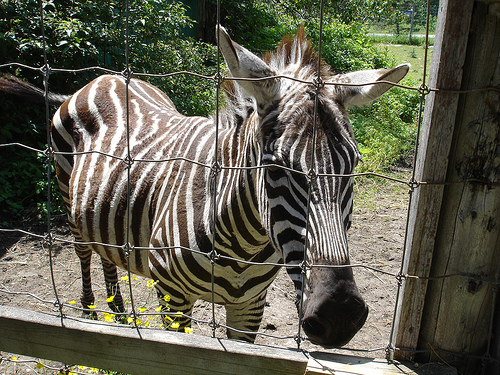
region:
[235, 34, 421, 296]
head of the zebra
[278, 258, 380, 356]
nose of the zebra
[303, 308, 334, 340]
nostril of the zebra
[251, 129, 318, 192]
eye of the animal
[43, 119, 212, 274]
black and white animal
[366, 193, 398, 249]
brown dirt under animal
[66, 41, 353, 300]
fence in front of animal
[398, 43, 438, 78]
green grass on the ground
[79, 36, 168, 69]
leaves on the tree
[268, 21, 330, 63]
hair on the zebra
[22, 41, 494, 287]
the zebra has stripes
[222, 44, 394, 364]
black and white zebra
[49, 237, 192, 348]
yellow flowers behind fence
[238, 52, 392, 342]
zebra looking at fence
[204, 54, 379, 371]
zebra in sunny scene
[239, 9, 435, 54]
green foliage behind fence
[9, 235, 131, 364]
sunlight on wooden post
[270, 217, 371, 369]
zebra's nose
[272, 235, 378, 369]
zebra's nose making shadow on wooden fence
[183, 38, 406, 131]
zebra's two ears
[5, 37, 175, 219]
zebra swishing tail in air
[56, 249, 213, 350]
small yellow flowers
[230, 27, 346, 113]
zebra has mohawk hair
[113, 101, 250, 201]
brown stripes not black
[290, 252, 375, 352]
zebras nose through the fence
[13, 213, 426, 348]
grass is dead near fence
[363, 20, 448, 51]
road or walk way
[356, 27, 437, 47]
over grown green grass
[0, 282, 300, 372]
wooden horizontal fence board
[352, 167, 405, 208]
patches of green grass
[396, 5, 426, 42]
wooden sign post road marker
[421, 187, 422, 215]
edge of a window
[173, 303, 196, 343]
part of a fence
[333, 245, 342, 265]
nose of a zebra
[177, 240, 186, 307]
leg of a zebra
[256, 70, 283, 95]
ear of a zebra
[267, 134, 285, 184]
eye of a zebra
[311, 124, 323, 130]
head of a zebra